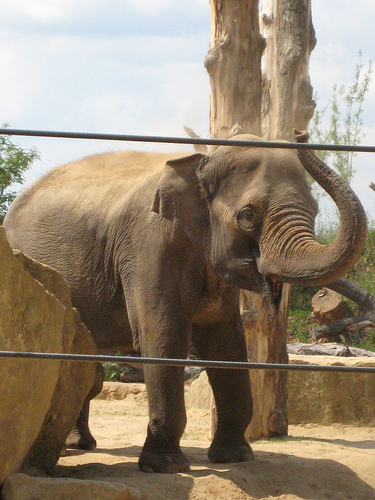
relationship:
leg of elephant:
[121, 316, 195, 478] [4, 119, 374, 474]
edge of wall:
[54, 301, 101, 356] [2, 220, 99, 487]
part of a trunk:
[296, 266, 310, 271] [258, 125, 373, 294]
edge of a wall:
[54, 301, 101, 356] [2, 220, 99, 487]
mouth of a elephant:
[260, 275, 292, 322] [4, 119, 374, 474]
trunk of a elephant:
[258, 125, 373, 294] [4, 119, 374, 474]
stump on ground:
[255, 371, 292, 439] [81, 397, 372, 499]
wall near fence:
[2, 220, 99, 487] [7, 129, 374, 164]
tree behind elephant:
[196, 0, 328, 140] [4, 119, 374, 474]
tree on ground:
[308, 289, 363, 343] [81, 397, 372, 499]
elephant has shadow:
[4, 119, 374, 474] [218, 446, 373, 499]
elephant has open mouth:
[4, 119, 374, 474] [260, 275, 292, 322]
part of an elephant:
[296, 266, 310, 271] [4, 119, 374, 474]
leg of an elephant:
[121, 316, 195, 478] [4, 119, 374, 474]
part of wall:
[296, 266, 310, 271] [2, 220, 99, 487]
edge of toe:
[184, 467, 187, 468] [165, 461, 192, 475]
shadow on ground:
[218, 446, 373, 499] [81, 397, 372, 499]